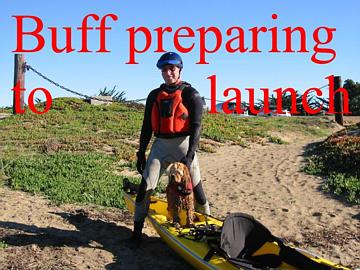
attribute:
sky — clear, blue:
[0, 0, 359, 108]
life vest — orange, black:
[151, 87, 192, 133]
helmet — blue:
[156, 51, 185, 69]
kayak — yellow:
[119, 185, 345, 268]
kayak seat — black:
[217, 213, 293, 269]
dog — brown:
[164, 161, 202, 228]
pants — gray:
[134, 135, 210, 222]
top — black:
[137, 81, 205, 165]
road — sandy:
[203, 119, 359, 265]